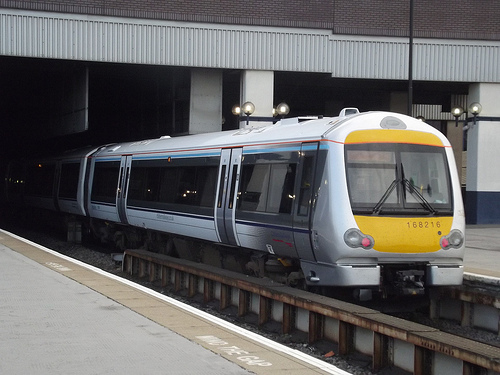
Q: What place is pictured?
A: It is a station.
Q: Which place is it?
A: It is a station.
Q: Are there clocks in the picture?
A: No, there are no clocks.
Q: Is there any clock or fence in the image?
A: No, there are no clocks or fences.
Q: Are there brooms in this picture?
A: No, there are no brooms.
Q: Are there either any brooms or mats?
A: No, there are no brooms or mats.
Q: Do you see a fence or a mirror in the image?
A: No, there are no fences or mirrors.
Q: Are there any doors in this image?
A: Yes, there are doors.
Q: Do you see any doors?
A: Yes, there are doors.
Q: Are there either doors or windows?
A: Yes, there are doors.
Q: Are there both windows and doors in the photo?
A: Yes, there are both doors and windows.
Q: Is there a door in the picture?
A: Yes, there is a door.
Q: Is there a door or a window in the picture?
A: Yes, there is a door.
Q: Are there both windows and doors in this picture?
A: Yes, there are both a door and a window.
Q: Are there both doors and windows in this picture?
A: Yes, there are both a door and a window.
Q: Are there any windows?
A: Yes, there is a window.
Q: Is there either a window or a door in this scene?
A: Yes, there is a window.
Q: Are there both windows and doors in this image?
A: Yes, there are both a window and a door.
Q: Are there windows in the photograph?
A: Yes, there is a window.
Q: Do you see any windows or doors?
A: Yes, there is a window.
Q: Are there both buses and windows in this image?
A: No, there is a window but no buses.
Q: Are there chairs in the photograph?
A: No, there are no chairs.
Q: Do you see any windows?
A: Yes, there is a window.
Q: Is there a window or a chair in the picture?
A: Yes, there is a window.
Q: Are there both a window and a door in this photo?
A: Yes, there are both a window and a door.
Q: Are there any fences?
A: No, there are no fences.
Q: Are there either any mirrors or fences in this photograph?
A: No, there are no fences or mirrors.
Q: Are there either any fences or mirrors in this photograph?
A: No, there are no fences or mirrors.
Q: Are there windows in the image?
A: Yes, there is a window.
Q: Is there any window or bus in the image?
A: Yes, there is a window.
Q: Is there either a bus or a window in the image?
A: Yes, there is a window.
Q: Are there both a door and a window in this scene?
A: Yes, there are both a window and a door.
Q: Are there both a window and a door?
A: Yes, there are both a window and a door.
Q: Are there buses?
A: No, there are no buses.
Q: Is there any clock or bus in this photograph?
A: No, there are no buses or clocks.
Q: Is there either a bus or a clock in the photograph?
A: No, there are no buses or clocks.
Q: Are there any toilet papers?
A: No, there are no toilet papers.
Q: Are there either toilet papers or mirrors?
A: No, there are no toilet papers or mirrors.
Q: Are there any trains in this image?
A: Yes, there is a train.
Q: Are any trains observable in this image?
A: Yes, there is a train.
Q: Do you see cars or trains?
A: Yes, there is a train.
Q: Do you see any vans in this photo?
A: No, there are no vans.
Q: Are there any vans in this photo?
A: No, there are no vans.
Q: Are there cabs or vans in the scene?
A: No, there are no vans or cabs.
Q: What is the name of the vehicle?
A: The vehicle is a train.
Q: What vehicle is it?
A: The vehicle is a train.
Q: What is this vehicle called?
A: This is a train.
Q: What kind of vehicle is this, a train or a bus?
A: This is a train.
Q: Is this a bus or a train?
A: This is a train.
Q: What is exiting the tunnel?
A: The train is exiting the tunnel.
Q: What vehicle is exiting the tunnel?
A: The vehicle is a train.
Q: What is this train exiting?
A: The train is exiting the tunnel.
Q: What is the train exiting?
A: The train is exiting the tunnel.